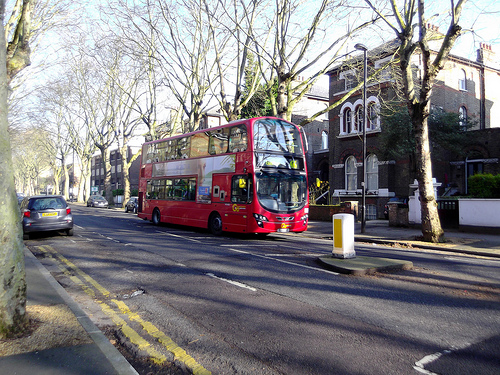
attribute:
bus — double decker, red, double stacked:
[136, 114, 311, 235]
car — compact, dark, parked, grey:
[21, 193, 75, 243]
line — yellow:
[43, 244, 213, 374]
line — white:
[205, 270, 259, 293]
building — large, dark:
[323, 19, 499, 220]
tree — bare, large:
[362, 0, 468, 244]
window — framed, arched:
[338, 101, 353, 137]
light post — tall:
[353, 41, 367, 236]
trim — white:
[331, 158, 396, 170]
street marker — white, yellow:
[330, 212, 357, 261]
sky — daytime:
[1, 0, 500, 179]